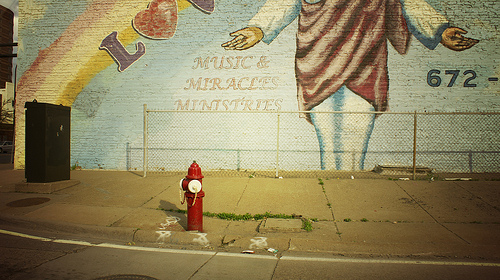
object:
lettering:
[172, 98, 280, 114]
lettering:
[183, 76, 278, 92]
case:
[24, 101, 70, 181]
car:
[0, 140, 14, 153]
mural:
[9, 0, 498, 173]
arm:
[401, 0, 450, 50]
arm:
[245, 0, 299, 44]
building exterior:
[12, 0, 499, 172]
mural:
[14, 0, 499, 174]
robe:
[295, 0, 407, 126]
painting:
[15, 0, 500, 174]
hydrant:
[176, 161, 203, 234]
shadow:
[155, 199, 187, 232]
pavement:
[0, 171, 499, 261]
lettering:
[188, 54, 273, 71]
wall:
[12, 0, 498, 172]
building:
[0, 5, 13, 141]